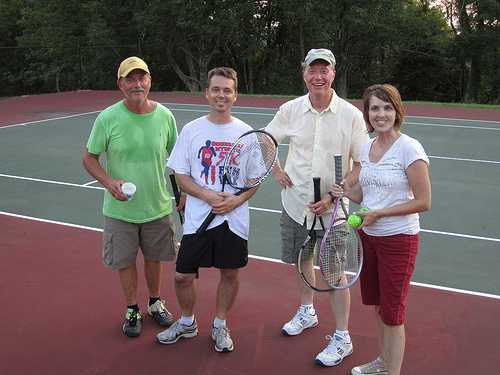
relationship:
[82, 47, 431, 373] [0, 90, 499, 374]
people on top of tennis court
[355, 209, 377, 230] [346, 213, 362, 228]
hand holding tennis ball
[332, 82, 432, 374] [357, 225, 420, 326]
woman wearing shorts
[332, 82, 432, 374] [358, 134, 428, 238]
woman wearing top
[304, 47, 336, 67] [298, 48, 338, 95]
hat on top of head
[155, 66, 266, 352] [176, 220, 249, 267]
man wearing shorts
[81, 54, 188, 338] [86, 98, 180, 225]
man wearing shirt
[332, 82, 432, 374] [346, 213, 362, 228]
woman holding tennis ball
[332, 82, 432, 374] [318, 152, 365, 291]
woman holding racket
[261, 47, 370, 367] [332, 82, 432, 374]
man standing next to woman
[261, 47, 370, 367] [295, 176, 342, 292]
man holding racket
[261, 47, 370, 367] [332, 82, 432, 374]
man next to woman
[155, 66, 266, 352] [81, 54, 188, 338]
man standing next to man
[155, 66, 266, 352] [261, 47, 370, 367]
man standing next to man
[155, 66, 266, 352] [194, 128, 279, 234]
man holding racket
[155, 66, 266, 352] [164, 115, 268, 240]
man wearing shirt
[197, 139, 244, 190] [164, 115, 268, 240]
advertisement on front of shirt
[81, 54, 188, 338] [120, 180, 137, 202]
man holding cup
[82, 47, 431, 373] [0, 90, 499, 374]
people standing on tennis court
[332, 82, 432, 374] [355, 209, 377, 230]
woman has hand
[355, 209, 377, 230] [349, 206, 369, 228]
hand holding tennis balls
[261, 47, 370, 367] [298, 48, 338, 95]
man has head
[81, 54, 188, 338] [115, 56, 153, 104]
man has head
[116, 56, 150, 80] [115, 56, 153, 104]
hat on top of head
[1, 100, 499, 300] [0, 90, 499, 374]
lines on top of tennis court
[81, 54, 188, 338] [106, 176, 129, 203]
man has hand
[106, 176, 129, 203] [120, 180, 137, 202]
hand holding cup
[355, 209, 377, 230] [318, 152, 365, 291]
hand holding racket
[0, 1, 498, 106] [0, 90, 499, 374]
trees lining tennis court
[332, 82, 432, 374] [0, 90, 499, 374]
woman standing on top of tennis court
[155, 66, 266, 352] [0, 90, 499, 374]
man standing on top of tennis court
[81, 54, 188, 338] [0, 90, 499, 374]
man standing on top of tennis court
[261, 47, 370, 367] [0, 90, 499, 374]
man standing on top of tennis court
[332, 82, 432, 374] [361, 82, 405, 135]
woman has hair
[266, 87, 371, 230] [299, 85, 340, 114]
shirt has collar